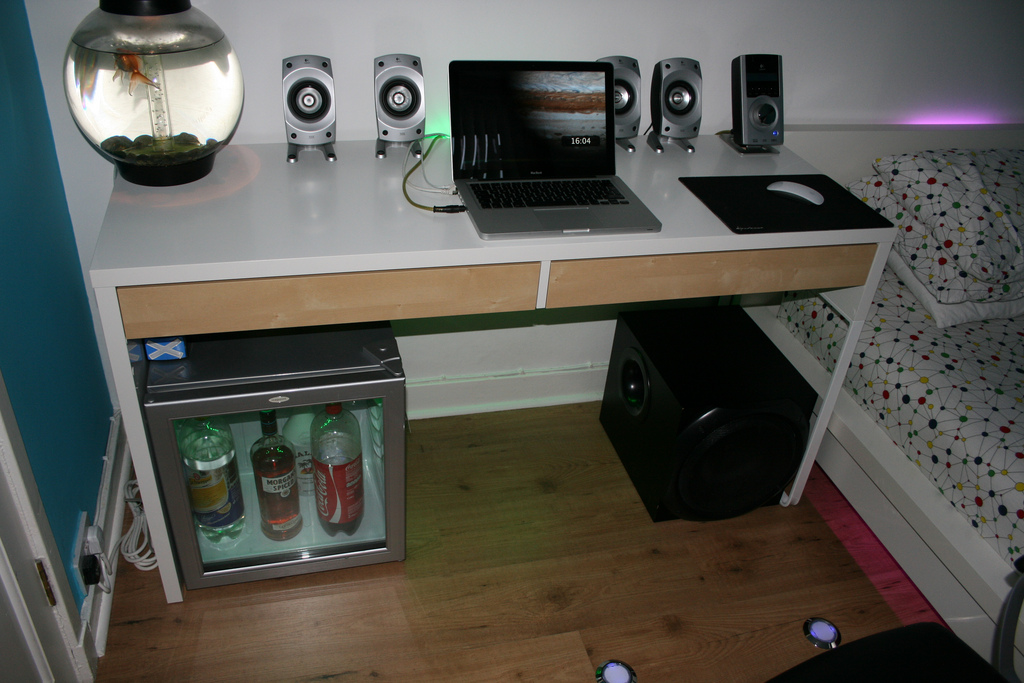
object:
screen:
[449, 60, 614, 182]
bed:
[740, 123, 1020, 665]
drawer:
[115, 263, 539, 341]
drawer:
[547, 243, 876, 308]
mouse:
[767, 181, 824, 206]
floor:
[95, 399, 990, 682]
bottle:
[280, 403, 316, 497]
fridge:
[135, 320, 408, 591]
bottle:
[247, 410, 304, 541]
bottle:
[176, 419, 245, 544]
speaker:
[282, 55, 337, 164]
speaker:
[373, 53, 425, 159]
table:
[296, 210, 307, 221]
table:
[266, 210, 302, 243]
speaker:
[595, 56, 642, 153]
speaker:
[646, 58, 703, 154]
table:
[244, 202, 255, 205]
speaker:
[718, 54, 783, 156]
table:
[299, 214, 305, 225]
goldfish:
[112, 48, 159, 96]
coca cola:
[310, 402, 362, 539]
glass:
[170, 398, 384, 564]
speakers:
[282, 54, 425, 165]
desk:
[90, 131, 901, 577]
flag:
[143, 339, 186, 360]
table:
[184, 214, 357, 271]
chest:
[235, 392, 363, 567]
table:
[150, 223, 356, 276]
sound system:
[595, 303, 816, 524]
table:
[236, 161, 387, 278]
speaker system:
[279, 53, 785, 164]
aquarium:
[65, 0, 246, 188]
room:
[0, 0, 1024, 683]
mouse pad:
[677, 173, 893, 235]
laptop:
[449, 60, 661, 241]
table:
[263, 191, 370, 261]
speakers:
[595, 54, 782, 157]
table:
[247, 196, 414, 266]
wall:
[24, 3, 1024, 422]